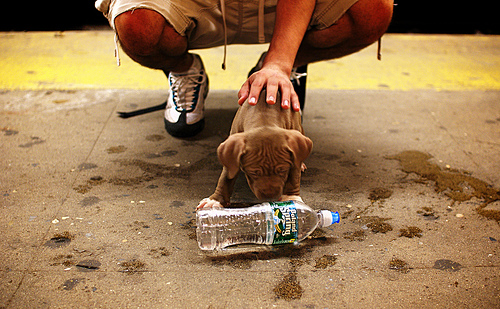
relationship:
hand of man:
[236, 66, 303, 110] [90, 1, 392, 132]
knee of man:
[105, 5, 182, 65] [90, 1, 392, 132]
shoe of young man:
[160, 66, 206, 139] [89, 0, 394, 140]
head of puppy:
[217, 125, 314, 207] [202, 86, 312, 209]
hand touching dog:
[236, 66, 303, 110] [208, 60, 312, 204]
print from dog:
[141, 242, 173, 262] [194, 87, 314, 210]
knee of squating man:
[105, 5, 182, 65] [90, 1, 392, 132]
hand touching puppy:
[236, 66, 303, 110] [191, 85, 314, 214]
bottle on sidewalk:
[190, 196, 342, 256] [0, 25, 500, 307]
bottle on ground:
[190, 196, 342, 256] [3, 32, 499, 302]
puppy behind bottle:
[208, 86, 310, 203] [173, 177, 388, 260]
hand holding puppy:
[236, 66, 303, 110] [203, 72, 332, 214]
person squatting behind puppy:
[91, 0, 356, 105] [224, 112, 302, 192]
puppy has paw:
[208, 86, 310, 203] [194, 191, 221, 216]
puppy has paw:
[208, 86, 310, 203] [195, 190, 225, 207]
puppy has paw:
[208, 86, 310, 203] [273, 186, 305, 206]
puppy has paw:
[208, 86, 310, 203] [293, 157, 309, 174]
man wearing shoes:
[90, 1, 392, 132] [113, 47, 349, 149]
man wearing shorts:
[90, 1, 392, 132] [90, 0, 392, 75]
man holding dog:
[90, 1, 392, 132] [194, 87, 314, 210]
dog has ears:
[198, 76, 325, 210] [218, 131, 313, 166]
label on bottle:
[269, 200, 304, 246] [178, 200, 372, 253]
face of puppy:
[216, 128, 311, 202] [198, 81, 315, 208]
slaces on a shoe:
[175, 74, 218, 88] [143, 66, 227, 140]